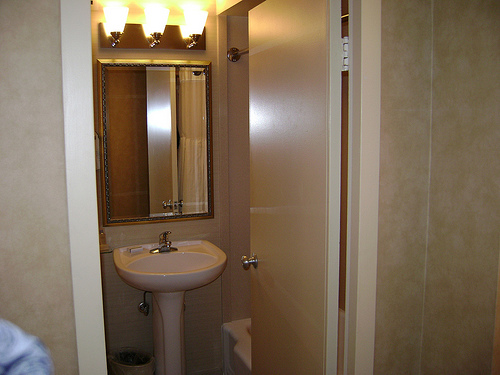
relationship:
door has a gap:
[247, 1, 337, 375] [335, 1, 351, 374]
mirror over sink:
[103, 64, 209, 220] [111, 239, 229, 375]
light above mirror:
[184, 6, 210, 37] [103, 64, 209, 220]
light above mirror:
[142, 4, 170, 41] [103, 64, 209, 220]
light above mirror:
[102, 2, 130, 35] [103, 64, 209, 220]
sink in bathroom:
[111, 239, 229, 375] [92, 2, 347, 374]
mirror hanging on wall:
[103, 64, 209, 220] [92, 2, 223, 374]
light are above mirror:
[101, 4, 130, 47] [103, 64, 209, 220]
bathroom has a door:
[92, 2, 347, 374] [247, 1, 337, 375]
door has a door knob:
[247, 1, 337, 375] [241, 252, 259, 272]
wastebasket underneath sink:
[106, 346, 156, 375] [111, 239, 229, 375]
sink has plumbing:
[111, 239, 229, 375] [138, 288, 151, 315]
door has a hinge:
[247, 1, 337, 375] [341, 35, 349, 73]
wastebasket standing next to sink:
[106, 346, 156, 375] [111, 239, 229, 375]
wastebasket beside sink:
[106, 346, 156, 375] [111, 239, 229, 375]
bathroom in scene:
[92, 2, 347, 374] [6, 0, 493, 372]